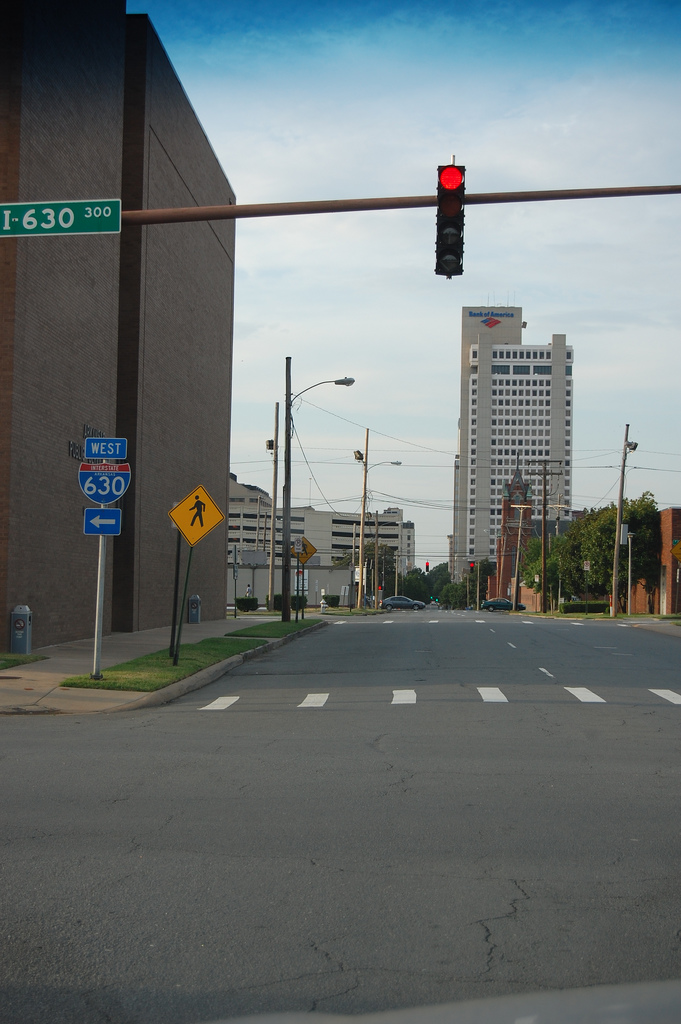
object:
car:
[379, 595, 426, 612]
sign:
[68, 424, 131, 537]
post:
[68, 424, 132, 686]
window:
[512, 380, 518, 388]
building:
[455, 304, 573, 611]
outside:
[0, 0, 681, 1024]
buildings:
[0, 0, 236, 655]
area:
[0, 616, 681, 1024]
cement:
[252, 821, 628, 1024]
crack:
[471, 879, 531, 977]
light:
[433, 154, 465, 278]